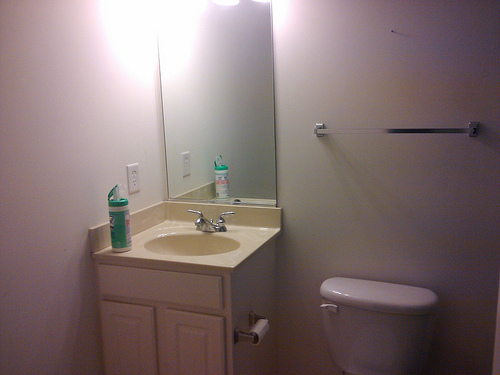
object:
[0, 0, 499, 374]
bathroom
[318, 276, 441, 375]
toilet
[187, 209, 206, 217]
handles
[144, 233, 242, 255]
sink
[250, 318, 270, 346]
roll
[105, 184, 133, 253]
wipes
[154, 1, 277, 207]
mirror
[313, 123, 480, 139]
towel rack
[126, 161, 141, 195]
electric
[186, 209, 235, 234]
water valve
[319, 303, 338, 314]
handle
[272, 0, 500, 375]
wall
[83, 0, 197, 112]
light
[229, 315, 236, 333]
holder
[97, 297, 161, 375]
door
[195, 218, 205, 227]
faucet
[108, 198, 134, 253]
container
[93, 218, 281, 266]
counter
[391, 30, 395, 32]
nail